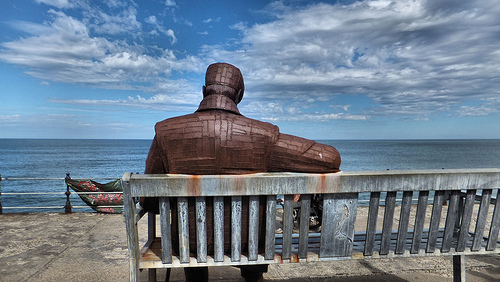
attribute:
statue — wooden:
[158, 64, 323, 172]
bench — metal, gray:
[120, 166, 498, 280]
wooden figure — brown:
[148, 60, 335, 259]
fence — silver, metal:
[0, 174, 130, 209]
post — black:
[62, 170, 73, 214]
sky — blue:
[7, 2, 461, 135]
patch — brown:
[142, 239, 159, 258]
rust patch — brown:
[308, 176, 333, 192]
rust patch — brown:
[175, 173, 205, 194]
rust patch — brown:
[182, 177, 210, 194]